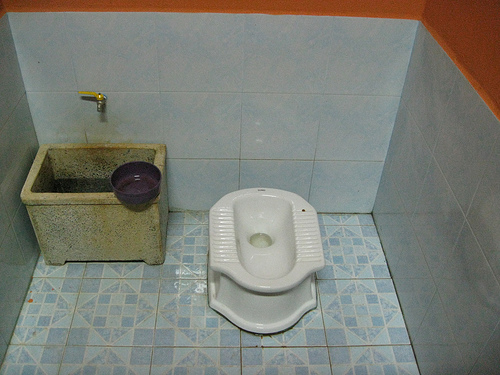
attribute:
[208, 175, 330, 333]
toilet — white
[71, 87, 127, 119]
faucet — gold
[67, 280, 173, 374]
floor — blue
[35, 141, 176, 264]
basin — gold, filled, dirty, far, blue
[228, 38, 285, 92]
wall — blue, orange